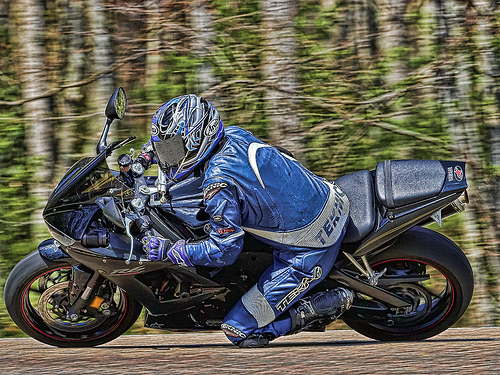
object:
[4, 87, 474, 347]
motorcycle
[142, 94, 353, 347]
rider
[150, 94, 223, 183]
helmet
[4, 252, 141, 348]
wheel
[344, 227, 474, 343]
wheel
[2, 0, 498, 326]
trees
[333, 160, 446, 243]
seat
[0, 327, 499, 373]
road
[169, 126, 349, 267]
jacket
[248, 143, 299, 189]
logo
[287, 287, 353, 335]
boot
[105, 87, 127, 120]
mirror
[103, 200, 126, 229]
mirror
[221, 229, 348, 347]
pants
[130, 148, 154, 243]
handlebars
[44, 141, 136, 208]
windshield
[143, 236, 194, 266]
gloves